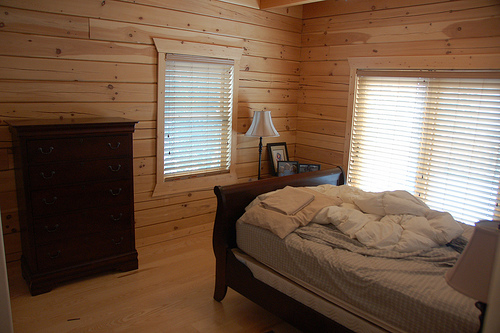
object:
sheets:
[235, 184, 480, 331]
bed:
[213, 165, 499, 332]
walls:
[7, 3, 296, 261]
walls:
[307, 5, 497, 64]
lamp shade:
[244, 109, 281, 138]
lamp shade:
[446, 219, 498, 305]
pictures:
[280, 162, 297, 175]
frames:
[277, 161, 300, 177]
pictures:
[273, 147, 285, 170]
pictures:
[302, 165, 316, 170]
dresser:
[11, 116, 140, 297]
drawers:
[30, 134, 131, 162]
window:
[150, 35, 236, 195]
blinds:
[167, 57, 228, 170]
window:
[344, 56, 499, 220]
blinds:
[353, 76, 496, 215]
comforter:
[317, 189, 460, 255]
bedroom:
[4, 1, 498, 333]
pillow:
[240, 185, 349, 239]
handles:
[40, 145, 54, 154]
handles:
[109, 142, 121, 150]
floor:
[11, 226, 305, 332]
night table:
[259, 171, 306, 179]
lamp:
[244, 110, 280, 181]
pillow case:
[259, 185, 314, 214]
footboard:
[210, 165, 348, 301]